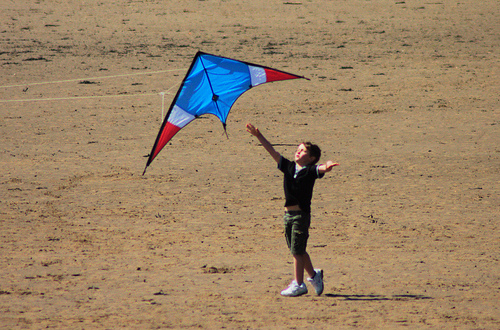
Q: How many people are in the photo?
A: One.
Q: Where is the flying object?
A: Above the boy.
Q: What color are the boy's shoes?
A: White.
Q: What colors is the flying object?
A: White, blue, red.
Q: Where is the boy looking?
A: Upward.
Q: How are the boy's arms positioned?
A: Sticking out.